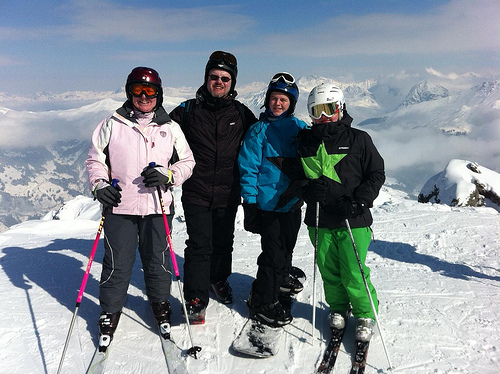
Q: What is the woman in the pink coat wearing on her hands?
A: Gloves.